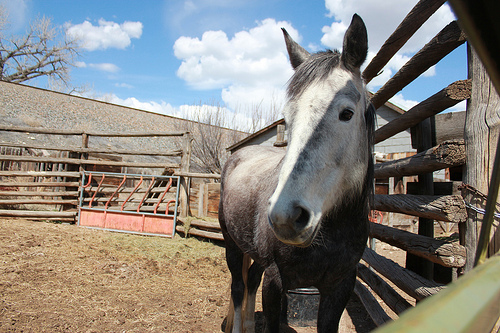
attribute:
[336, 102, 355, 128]
eye — dark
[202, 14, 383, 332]
horse — grey, brown, white, black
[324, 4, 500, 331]
fence — brown, wood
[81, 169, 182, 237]
gate — orange, red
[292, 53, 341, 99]
mane — grey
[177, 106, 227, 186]
trees — small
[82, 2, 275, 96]
sky — blue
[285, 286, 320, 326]
bucket — small, black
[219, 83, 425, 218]
house — blue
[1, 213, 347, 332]
grass — dry